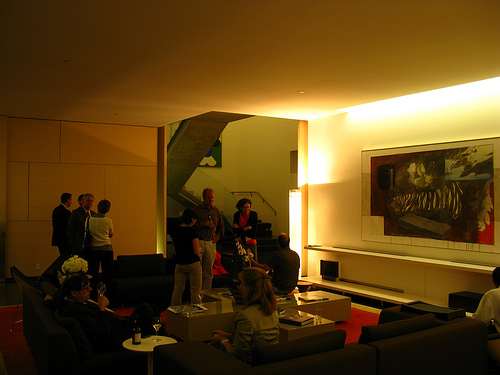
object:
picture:
[360, 137, 499, 254]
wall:
[306, 76, 500, 310]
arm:
[232, 213, 258, 235]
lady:
[232, 223, 239, 228]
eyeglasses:
[82, 284, 90, 290]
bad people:
[84, 199, 117, 301]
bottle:
[132, 320, 141, 345]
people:
[232, 198, 258, 243]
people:
[171, 208, 203, 306]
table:
[279, 307, 336, 330]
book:
[167, 304, 209, 318]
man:
[192, 188, 225, 290]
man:
[55, 274, 162, 340]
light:
[288, 189, 303, 280]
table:
[167, 290, 351, 319]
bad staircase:
[166, 111, 255, 238]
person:
[211, 268, 280, 362]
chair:
[151, 305, 488, 375]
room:
[0, 0, 499, 375]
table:
[123, 336, 178, 352]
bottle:
[206, 214, 213, 238]